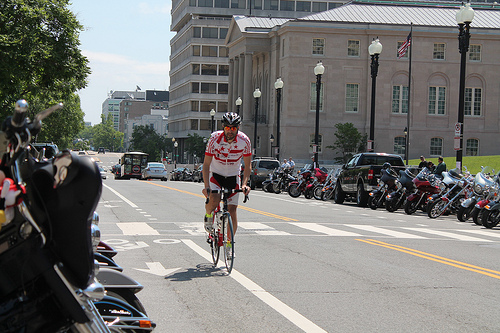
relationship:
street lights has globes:
[262, 8, 471, 173] [269, 3, 476, 88]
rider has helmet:
[202, 112, 252, 261] [215, 112, 252, 130]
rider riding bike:
[202, 112, 252, 261] [203, 185, 249, 275]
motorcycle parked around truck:
[362, 157, 489, 231] [331, 150, 416, 230]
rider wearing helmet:
[189, 101, 265, 217] [215, 97, 250, 127]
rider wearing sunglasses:
[189, 101, 265, 217] [221, 124, 243, 131]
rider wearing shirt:
[202, 112, 252, 261] [206, 130, 253, 177]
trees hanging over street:
[10, 1, 81, 170] [77, 150, 497, 331]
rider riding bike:
[202, 112, 252, 261] [211, 187, 247, 272]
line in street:
[131, 180, 499, 281] [77, 150, 497, 331]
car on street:
[141, 160, 168, 180] [77, 150, 497, 331]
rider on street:
[202, 112, 252, 261] [252, 218, 493, 331]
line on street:
[104, 178, 499, 333] [245, 214, 473, 295]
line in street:
[104, 178, 499, 333] [77, 150, 497, 331]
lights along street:
[200, 10, 486, 190] [305, 237, 442, 301]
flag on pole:
[394, 27, 414, 58] [403, 20, 416, 162]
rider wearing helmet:
[202, 112, 252, 261] [220, 113, 240, 129]